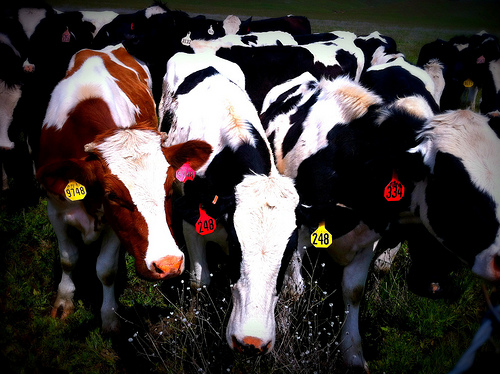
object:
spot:
[303, 82, 318, 93]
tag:
[462, 81, 474, 88]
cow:
[417, 37, 492, 104]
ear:
[295, 197, 357, 238]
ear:
[177, 185, 234, 222]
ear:
[161, 137, 214, 177]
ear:
[36, 155, 103, 203]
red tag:
[385, 173, 403, 202]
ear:
[410, 139, 435, 164]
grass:
[371, 286, 451, 363]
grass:
[3, 195, 498, 370]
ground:
[374, 175, 396, 227]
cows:
[36, 17, 489, 344]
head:
[383, 103, 498, 306]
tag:
[380, 180, 412, 208]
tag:
[176, 161, 196, 182]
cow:
[16, 40, 187, 350]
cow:
[167, 50, 300, 355]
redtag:
[176, 158, 197, 182]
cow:
[261, 68, 498, 371]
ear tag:
[195, 207, 215, 236]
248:
[196, 217, 213, 232]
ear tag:
[66, 179, 87, 202]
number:
[65, 182, 87, 200]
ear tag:
[310, 221, 334, 248]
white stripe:
[99, 132, 190, 261]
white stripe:
[224, 174, 302, 347]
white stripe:
[457, 129, 499, 217]